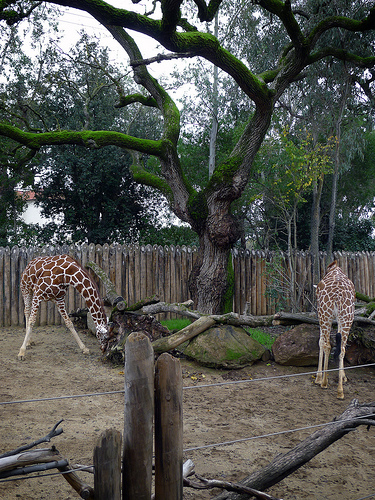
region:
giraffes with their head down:
[40, 210, 367, 418]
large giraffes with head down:
[24, 220, 367, 401]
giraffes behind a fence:
[37, 213, 372, 425]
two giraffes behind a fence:
[26, 201, 374, 389]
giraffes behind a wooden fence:
[8, 204, 369, 436]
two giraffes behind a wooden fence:
[27, 193, 364, 416]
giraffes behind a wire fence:
[27, 271, 373, 497]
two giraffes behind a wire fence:
[8, 218, 306, 495]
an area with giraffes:
[54, 219, 373, 365]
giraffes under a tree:
[20, 200, 373, 431]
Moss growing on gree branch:
[4, 122, 37, 142]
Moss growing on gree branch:
[31, 128, 62, 151]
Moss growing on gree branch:
[63, 125, 99, 153]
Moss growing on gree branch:
[90, 121, 142, 149]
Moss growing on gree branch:
[128, 131, 179, 157]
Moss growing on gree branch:
[124, 156, 154, 183]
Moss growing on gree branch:
[143, 166, 192, 208]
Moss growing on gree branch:
[201, 159, 269, 186]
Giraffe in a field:
[300, 231, 360, 402]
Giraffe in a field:
[8, 244, 111, 367]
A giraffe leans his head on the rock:
[10, 246, 112, 382]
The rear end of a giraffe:
[313, 253, 362, 414]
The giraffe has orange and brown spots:
[11, 251, 115, 359]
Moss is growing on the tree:
[221, 244, 241, 323]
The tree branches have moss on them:
[11, 74, 267, 225]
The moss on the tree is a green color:
[15, 115, 181, 192]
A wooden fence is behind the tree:
[5, 241, 374, 319]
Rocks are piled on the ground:
[170, 311, 371, 371]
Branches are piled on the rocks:
[139, 281, 370, 328]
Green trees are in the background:
[14, 64, 370, 247]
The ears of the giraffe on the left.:
[101, 322, 110, 332]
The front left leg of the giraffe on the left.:
[15, 295, 40, 363]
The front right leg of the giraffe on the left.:
[56, 300, 90, 356]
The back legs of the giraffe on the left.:
[21, 294, 36, 350]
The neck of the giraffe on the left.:
[75, 280, 106, 319]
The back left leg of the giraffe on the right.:
[323, 324, 328, 388]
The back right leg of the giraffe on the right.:
[336, 315, 344, 394]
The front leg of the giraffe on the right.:
[317, 324, 335, 386]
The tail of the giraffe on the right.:
[335, 293, 343, 360]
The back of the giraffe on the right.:
[323, 265, 351, 295]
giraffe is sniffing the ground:
[45, 254, 121, 377]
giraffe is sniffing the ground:
[78, 281, 137, 379]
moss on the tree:
[20, 115, 153, 156]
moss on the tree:
[3, 105, 180, 188]